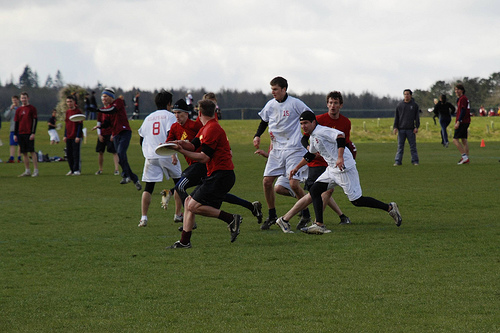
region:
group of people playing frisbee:
[127, 70, 426, 272]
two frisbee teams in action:
[128, 68, 415, 278]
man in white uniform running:
[290, 111, 403, 248]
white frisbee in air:
[59, 107, 90, 124]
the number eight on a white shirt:
[148, 97, 170, 141]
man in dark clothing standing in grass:
[377, 73, 431, 193]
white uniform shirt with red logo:
[250, 95, 304, 155]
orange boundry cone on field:
[472, 136, 493, 158]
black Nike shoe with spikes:
[225, 210, 249, 248]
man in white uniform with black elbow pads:
[285, 104, 365, 238]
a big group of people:
[14, 77, 497, 287]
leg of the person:
[141, 197, 241, 237]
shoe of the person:
[168, 216, 203, 251]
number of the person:
[147, 110, 169, 144]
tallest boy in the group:
[236, 62, 327, 252]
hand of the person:
[243, 114, 263, 160]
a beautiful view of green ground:
[17, 184, 455, 330]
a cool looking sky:
[21, 0, 466, 141]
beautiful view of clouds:
[84, 17, 466, 137]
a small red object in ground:
[458, 129, 494, 201]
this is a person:
[15, 92, 50, 179]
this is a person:
[58, 91, 85, 175]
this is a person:
[143, 92, 190, 208]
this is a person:
[188, 103, 245, 228]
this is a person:
[302, 112, 362, 225]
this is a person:
[261, 69, 298, 211]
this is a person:
[389, 85, 426, 162]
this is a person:
[448, 85, 483, 174]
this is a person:
[431, 90, 456, 152]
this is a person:
[128, 92, 141, 127]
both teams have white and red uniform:
[8, 72, 478, 273]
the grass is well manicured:
[26, 195, 126, 325]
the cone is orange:
[475, 135, 495, 151]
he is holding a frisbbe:
[140, 110, 248, 237]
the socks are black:
[305, 171, 381, 213]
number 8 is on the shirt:
[131, 110, 172, 167]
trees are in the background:
[210, 90, 255, 115]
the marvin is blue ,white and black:
[95, 81, 115, 106]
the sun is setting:
[5, 0, 490, 330]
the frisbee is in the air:
[65, 108, 101, 129]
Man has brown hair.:
[263, 67, 292, 105]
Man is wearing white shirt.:
[272, 103, 299, 160]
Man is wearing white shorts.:
[266, 150, 292, 195]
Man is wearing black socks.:
[260, 201, 277, 220]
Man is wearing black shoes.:
[259, 210, 281, 250]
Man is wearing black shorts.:
[187, 167, 244, 232]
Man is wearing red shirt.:
[206, 135, 234, 168]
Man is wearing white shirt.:
[326, 142, 353, 181]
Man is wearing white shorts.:
[331, 153, 358, 205]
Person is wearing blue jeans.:
[390, 135, 426, 138]